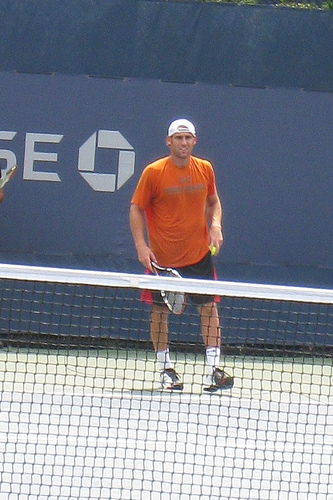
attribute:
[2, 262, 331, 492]
net — white, black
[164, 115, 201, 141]
cap — backwards, white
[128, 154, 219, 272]
t-shirt — orange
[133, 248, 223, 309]
shorts — black, red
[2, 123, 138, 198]
logo — white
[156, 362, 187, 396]
sneaker — white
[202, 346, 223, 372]
sock — white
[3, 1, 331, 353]
tarp — blue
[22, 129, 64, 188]
e — white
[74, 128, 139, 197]
symbol — white